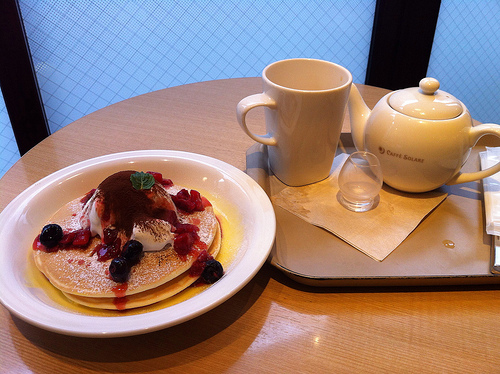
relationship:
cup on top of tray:
[237, 58, 352, 186] [246, 133, 499, 287]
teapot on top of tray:
[349, 77, 499, 194] [246, 133, 499, 287]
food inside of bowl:
[29, 170, 243, 317] [1, 150, 276, 339]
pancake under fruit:
[62, 216, 222, 311] [190, 251, 214, 277]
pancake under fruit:
[30, 186, 219, 310] [109, 258, 129, 283]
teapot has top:
[349, 77, 499, 194] [387, 77, 462, 120]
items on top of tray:
[479, 147, 499, 277] [246, 133, 499, 287]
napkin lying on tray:
[271, 152, 449, 261] [246, 133, 499, 287]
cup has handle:
[237, 58, 352, 186] [237, 92, 276, 146]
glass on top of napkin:
[337, 151, 384, 212] [271, 152, 449, 261]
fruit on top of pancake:
[122, 241, 143, 262] [30, 186, 219, 310]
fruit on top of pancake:
[74, 230, 90, 247] [30, 186, 219, 310]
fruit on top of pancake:
[40, 224, 62, 247] [30, 186, 219, 310]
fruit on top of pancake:
[179, 189, 188, 201] [30, 186, 219, 310]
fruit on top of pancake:
[174, 234, 190, 254] [30, 186, 219, 310]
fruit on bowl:
[174, 234, 190, 254] [1, 150, 276, 339]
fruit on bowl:
[74, 230, 90, 247] [1, 150, 276, 339]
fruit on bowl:
[179, 189, 188, 201] [1, 150, 276, 339]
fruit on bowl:
[40, 224, 62, 247] [1, 150, 276, 339]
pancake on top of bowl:
[62, 216, 222, 311] [1, 150, 276, 339]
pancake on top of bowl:
[30, 186, 219, 310] [1, 150, 276, 339]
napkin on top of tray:
[271, 152, 449, 261] [246, 133, 499, 287]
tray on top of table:
[246, 133, 499, 287] [1, 76, 499, 373]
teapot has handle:
[349, 77, 499, 194] [446, 124, 499, 184]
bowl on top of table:
[1, 150, 276, 339] [1, 76, 499, 373]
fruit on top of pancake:
[190, 251, 214, 277] [62, 216, 222, 311]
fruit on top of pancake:
[109, 258, 129, 283] [30, 186, 219, 310]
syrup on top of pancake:
[69, 170, 207, 309] [30, 186, 219, 310]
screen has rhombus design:
[1, 1, 499, 181] [118, 27, 134, 43]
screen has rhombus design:
[1, 1, 499, 181] [190, 20, 203, 35]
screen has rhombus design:
[1, 1, 499, 181] [253, 28, 267, 41]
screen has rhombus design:
[1, 1, 499, 181] [304, 30, 315, 45]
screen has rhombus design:
[1, 1, 499, 181] [165, 47, 179, 61]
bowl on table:
[1, 150, 276, 339] [1, 76, 499, 373]